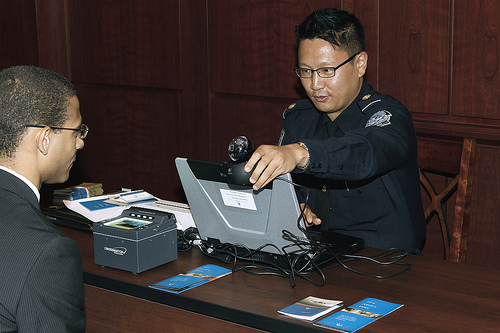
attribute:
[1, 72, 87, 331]
man — sitting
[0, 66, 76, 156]
man hair — cut, black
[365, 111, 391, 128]
badge — blue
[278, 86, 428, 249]
shirt — blue, navy blue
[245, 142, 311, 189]
hand — showing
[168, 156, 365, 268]
computer — black, silver, laptop, gray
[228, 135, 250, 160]
camera — round, black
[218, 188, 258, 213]
label — white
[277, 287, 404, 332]
pamphlets — blue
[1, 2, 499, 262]
wall — brown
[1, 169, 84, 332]
suit — dark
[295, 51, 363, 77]
eyeglasses — wire framed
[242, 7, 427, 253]
security officer — uniformed, sitting, asian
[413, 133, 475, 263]
chair — wooden, brown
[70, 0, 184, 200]
panelling — dark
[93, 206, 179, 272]
box — grey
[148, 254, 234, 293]
pamphlet — blue